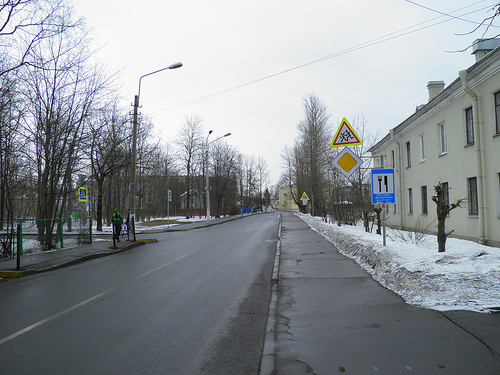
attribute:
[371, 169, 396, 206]
sign — blue, here, triangular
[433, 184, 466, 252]
tree — here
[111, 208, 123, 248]
person — talking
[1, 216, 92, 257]
fence — green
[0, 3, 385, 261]
trees — tall, dry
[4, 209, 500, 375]
street — empty, here, clear, tarmacked, present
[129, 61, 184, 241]
street lamp — here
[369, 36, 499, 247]
building — short, present, cream, brick, here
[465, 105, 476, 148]
window — here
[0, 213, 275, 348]
strip — white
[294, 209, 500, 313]
snow — here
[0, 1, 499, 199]
sky — white, here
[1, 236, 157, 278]
sidewalk — clear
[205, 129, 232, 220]
street lamp — here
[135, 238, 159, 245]
curb — yellow